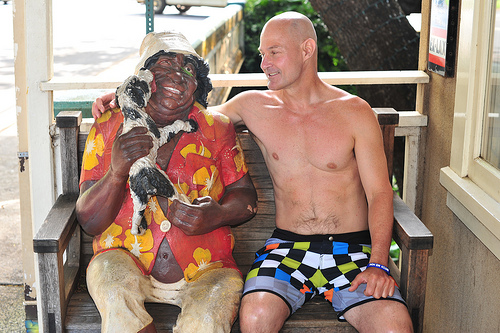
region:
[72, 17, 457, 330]
two men sitting on bench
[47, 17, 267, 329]
one man wearing a hat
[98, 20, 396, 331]
a man sitting next to statue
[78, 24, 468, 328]
a man sitting next to statue on bench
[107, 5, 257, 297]
statue of a man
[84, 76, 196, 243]
a statue of a dog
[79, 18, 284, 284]
dog licking mans face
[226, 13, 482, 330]
man wearing swim trunks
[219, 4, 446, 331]
man wearing no shirt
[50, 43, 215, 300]
statue wearing hawaiin shirt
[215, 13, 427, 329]
a person sits in a bench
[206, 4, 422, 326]
person wears multicolor shorts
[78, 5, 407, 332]
person is hugging a statue of a man of color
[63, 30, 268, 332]
statue of a man holding a dog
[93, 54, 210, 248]
statue dog is white and black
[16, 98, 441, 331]
bench is made of wood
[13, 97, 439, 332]
bench has armrest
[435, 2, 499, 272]
a window in front a bench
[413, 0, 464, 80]
a board displaying information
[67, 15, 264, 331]
statue of man has a hat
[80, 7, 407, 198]
man is hugging a statue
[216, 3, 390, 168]
man is smiling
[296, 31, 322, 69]
a left ear of man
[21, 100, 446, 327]
bench is made is brown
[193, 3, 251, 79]
a fence on side of street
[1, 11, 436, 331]
bench is on a porch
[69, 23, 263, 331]
statue has red shirt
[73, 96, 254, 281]
shirt is red and yellow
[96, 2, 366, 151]
statue and man are smiling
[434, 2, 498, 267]
window has yellow frame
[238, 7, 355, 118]
face of the person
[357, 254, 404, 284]
a band tied to hand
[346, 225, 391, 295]
a man tying a band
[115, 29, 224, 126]
face of the black person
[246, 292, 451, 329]
legs of the person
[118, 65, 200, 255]
a beautiful dog holding by person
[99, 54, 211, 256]
a dog kissing the man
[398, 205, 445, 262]
a part of the handle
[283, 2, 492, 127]
a large group of trees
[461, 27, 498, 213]
a part of the window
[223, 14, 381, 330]
shirtless man in swim trunks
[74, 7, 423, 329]
man posing with statue on bench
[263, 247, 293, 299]
colorful checkered pattern on swim trunks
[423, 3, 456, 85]
sign mounted on wall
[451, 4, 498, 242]
window with white painted frame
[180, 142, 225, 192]
yellow floral pattern on red shirt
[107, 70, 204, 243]
statue has a pet dog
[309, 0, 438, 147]
large tree trunk behind porch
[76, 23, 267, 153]
man wrapped arm around statue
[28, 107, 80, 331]
wood bench with arm rest